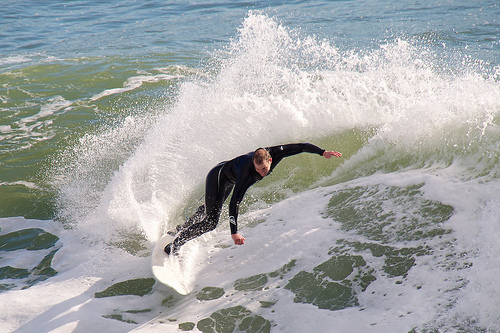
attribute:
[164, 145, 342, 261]
man — leaning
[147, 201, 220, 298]
surfboard — white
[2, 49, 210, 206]
waves — foamy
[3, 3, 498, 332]
water — sunlit, blue, green, white, murky, ocean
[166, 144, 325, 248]
wet suit — black, tight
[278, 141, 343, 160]
arm — extended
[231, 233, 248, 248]
hand — raised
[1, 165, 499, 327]
foam — white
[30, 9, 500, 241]
spray — white, rough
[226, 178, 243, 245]
arm — extended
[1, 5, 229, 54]
water — calm